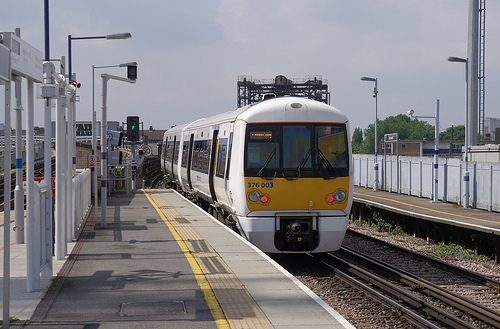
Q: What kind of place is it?
A: It is a station.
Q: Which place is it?
A: It is a station.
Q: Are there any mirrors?
A: No, there are no mirrors.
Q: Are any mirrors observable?
A: No, there are no mirrors.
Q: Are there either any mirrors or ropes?
A: No, there are no mirrors or ropes.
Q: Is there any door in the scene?
A: Yes, there are doors.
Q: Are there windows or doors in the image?
A: Yes, there are doors.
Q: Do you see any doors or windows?
A: Yes, there are doors.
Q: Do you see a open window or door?
A: Yes, there are open doors.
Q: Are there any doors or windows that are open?
A: Yes, the doors are open.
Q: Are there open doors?
A: Yes, there are open doors.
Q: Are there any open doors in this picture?
A: Yes, there are open doors.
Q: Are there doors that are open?
A: Yes, there are doors that are open.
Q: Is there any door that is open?
A: Yes, there are doors that are open.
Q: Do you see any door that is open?
A: Yes, there are doors that are open.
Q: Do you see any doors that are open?
A: Yes, there are doors that are open.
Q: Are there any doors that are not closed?
A: Yes, there are open doors.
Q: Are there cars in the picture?
A: No, there are no cars.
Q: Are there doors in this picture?
A: Yes, there is a door.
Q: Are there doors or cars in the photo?
A: Yes, there is a door.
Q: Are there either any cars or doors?
A: Yes, there is a door.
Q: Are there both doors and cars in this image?
A: No, there is a door but no cars.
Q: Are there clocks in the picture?
A: No, there are no clocks.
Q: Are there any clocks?
A: No, there are no clocks.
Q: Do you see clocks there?
A: No, there are no clocks.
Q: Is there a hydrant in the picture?
A: No, there are no fire hydrants.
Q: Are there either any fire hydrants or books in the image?
A: No, there are no fire hydrants or books.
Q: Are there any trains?
A: Yes, there is a train.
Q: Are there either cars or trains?
A: Yes, there is a train.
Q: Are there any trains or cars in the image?
A: Yes, there is a train.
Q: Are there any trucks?
A: No, there are no trucks.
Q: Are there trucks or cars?
A: No, there are no trucks or cars.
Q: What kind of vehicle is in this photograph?
A: The vehicle is a train.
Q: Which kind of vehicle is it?
A: The vehicle is a train.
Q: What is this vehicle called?
A: This is a train.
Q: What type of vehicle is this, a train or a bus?
A: This is a train.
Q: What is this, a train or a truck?
A: This is a train.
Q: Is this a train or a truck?
A: This is a train.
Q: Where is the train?
A: The train is at the station.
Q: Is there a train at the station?
A: Yes, there is a train at the station.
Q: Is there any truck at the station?
A: No, there is a train at the station.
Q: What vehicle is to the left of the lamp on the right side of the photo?
A: The vehicle is a train.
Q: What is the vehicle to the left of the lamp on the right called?
A: The vehicle is a train.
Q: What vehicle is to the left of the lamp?
A: The vehicle is a train.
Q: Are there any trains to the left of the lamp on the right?
A: Yes, there is a train to the left of the lamp.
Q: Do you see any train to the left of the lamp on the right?
A: Yes, there is a train to the left of the lamp.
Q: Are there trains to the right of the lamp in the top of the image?
A: No, the train is to the left of the lamp.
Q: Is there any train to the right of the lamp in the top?
A: No, the train is to the left of the lamp.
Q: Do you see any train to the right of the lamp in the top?
A: No, the train is to the left of the lamp.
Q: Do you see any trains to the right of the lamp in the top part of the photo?
A: No, the train is to the left of the lamp.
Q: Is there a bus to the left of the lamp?
A: No, there is a train to the left of the lamp.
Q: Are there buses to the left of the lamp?
A: No, there is a train to the left of the lamp.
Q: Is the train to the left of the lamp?
A: Yes, the train is to the left of the lamp.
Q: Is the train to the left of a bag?
A: No, the train is to the left of the lamp.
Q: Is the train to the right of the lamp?
A: No, the train is to the left of the lamp.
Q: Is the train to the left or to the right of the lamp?
A: The train is to the left of the lamp.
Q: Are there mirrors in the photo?
A: No, there are no mirrors.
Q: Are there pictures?
A: No, there are no pictures.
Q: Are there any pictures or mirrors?
A: No, there are no pictures or mirrors.